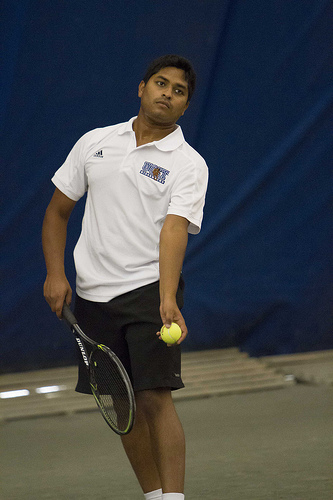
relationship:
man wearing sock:
[39, 52, 208, 498] [142, 488, 162, 498]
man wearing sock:
[39, 52, 208, 498] [161, 491, 185, 498]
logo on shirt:
[138, 160, 170, 185] [44, 114, 210, 302]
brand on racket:
[73, 332, 88, 367] [60, 299, 137, 436]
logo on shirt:
[93, 148, 106, 160] [44, 114, 210, 302]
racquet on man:
[51, 295, 139, 432] [39, 52, 208, 498]